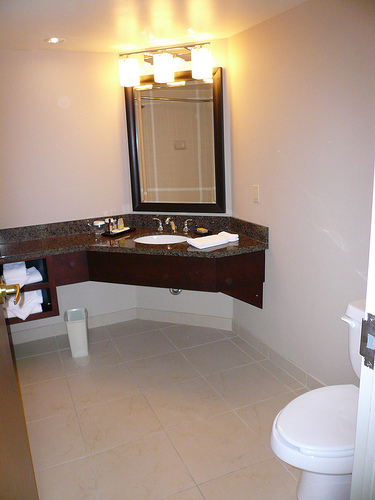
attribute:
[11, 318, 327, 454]
floor — beige, tile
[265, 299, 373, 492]
toilet — porcelain, white, ceramic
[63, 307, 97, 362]
trash bin — white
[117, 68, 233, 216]
mirror — framed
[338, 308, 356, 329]
plastic handle — white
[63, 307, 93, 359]
trash can — white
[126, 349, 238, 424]
tile — white, beige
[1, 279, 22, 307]
door handle — brass, gold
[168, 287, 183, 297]
pipe — metal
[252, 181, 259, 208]
outlet — mounted, white, electrical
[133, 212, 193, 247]
sink — white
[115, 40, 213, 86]
light — round, yellow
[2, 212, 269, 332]
counter — granite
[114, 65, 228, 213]
frame — wooden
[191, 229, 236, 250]
towels — white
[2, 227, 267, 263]
counter top — brown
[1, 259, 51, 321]
towels — white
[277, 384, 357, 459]
lid — white